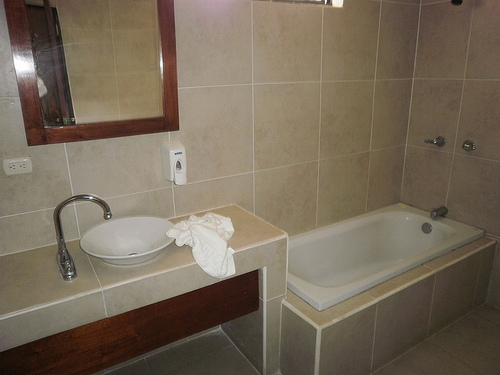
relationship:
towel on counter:
[165, 211, 237, 281] [1, 202, 288, 317]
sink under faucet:
[77, 215, 178, 268] [51, 193, 113, 280]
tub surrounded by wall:
[288, 199, 485, 311] [0, 0, 425, 257]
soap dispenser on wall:
[160, 139, 189, 190] [0, 0, 425, 257]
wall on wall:
[0, 0, 499, 261] [0, 0, 425, 257]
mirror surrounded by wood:
[22, 0, 168, 129] [1, 0, 180, 147]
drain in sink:
[126, 252, 139, 257] [77, 215, 178, 268]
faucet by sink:
[51, 193, 113, 280] [77, 215, 178, 268]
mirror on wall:
[22, 0, 168, 129] [0, 0, 425, 257]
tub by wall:
[288, 199, 485, 311] [0, 0, 425, 257]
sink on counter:
[77, 215, 178, 268] [1, 202, 288, 317]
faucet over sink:
[51, 193, 113, 280] [77, 215, 178, 268]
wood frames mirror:
[1, 0, 180, 147] [22, 0, 168, 129]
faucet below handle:
[429, 204, 449, 220] [421, 135, 447, 152]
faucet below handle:
[429, 204, 449, 220] [460, 139, 477, 155]